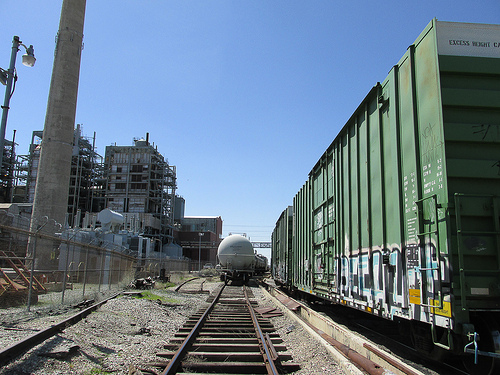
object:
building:
[14, 121, 187, 283]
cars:
[270, 18, 498, 373]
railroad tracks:
[140, 277, 301, 373]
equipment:
[63, 205, 165, 284]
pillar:
[23, 1, 88, 276]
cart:
[213, 232, 272, 286]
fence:
[2, 204, 211, 326]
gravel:
[101, 306, 112, 312]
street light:
[15, 37, 37, 68]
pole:
[0, 35, 20, 139]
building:
[101, 129, 180, 277]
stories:
[126, 153, 147, 196]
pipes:
[0, 290, 122, 371]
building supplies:
[129, 273, 156, 291]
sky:
[110, 10, 356, 110]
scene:
[1, 0, 499, 370]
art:
[323, 240, 453, 328]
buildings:
[182, 215, 222, 272]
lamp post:
[0, 34, 36, 164]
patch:
[127, 320, 142, 329]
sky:
[0, 1, 59, 36]